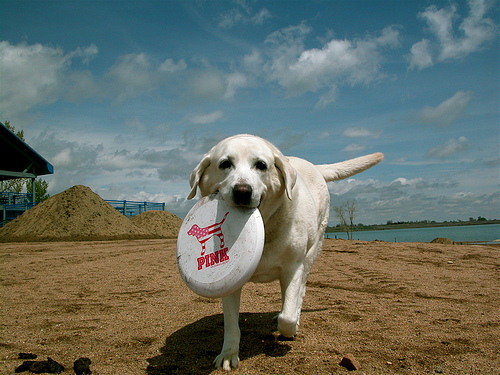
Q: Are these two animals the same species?
A: Yes, all the animals are dogs.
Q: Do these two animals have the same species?
A: Yes, all the animals are dogs.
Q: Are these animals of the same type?
A: Yes, all the animals are dogs.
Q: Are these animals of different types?
A: No, all the animals are dogs.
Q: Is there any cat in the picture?
A: No, there are no cats.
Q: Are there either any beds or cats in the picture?
A: No, there are no cats or beds.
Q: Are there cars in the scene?
A: No, there are no cars.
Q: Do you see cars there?
A: No, there are no cars.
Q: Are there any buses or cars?
A: No, there are no cars or buses.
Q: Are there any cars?
A: No, there are no cars.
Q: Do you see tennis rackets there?
A: No, there are no tennis rackets.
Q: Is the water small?
A: Yes, the water is small.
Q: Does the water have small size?
A: Yes, the water is small.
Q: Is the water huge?
A: No, the water is small.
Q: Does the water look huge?
A: No, the water is small.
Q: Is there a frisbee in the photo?
A: Yes, there is a frisbee.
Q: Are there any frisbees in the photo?
A: Yes, there is a frisbee.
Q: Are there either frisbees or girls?
A: Yes, there is a frisbee.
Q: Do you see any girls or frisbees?
A: Yes, there is a frisbee.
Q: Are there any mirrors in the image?
A: No, there are no mirrors.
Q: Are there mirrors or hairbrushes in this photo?
A: No, there are no mirrors or hairbrushes.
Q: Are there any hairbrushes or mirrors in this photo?
A: No, there are no mirrors or hairbrushes.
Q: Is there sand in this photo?
A: Yes, there is sand.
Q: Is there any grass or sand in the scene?
A: Yes, there is sand.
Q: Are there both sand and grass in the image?
A: No, there is sand but no grass.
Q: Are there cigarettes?
A: No, there are no cigarettes.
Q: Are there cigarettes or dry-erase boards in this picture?
A: No, there are no cigarettes or dry-erase boards.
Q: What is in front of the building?
A: The sand is in front of the building.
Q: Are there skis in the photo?
A: No, there are no skis.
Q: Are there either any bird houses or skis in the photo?
A: No, there are no skis or bird houses.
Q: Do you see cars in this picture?
A: No, there are no cars.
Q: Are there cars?
A: No, there are no cars.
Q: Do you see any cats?
A: No, there are no cats.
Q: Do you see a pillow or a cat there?
A: No, there are no cats or pillows.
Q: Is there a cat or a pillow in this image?
A: No, there are no cats or pillows.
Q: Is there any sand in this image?
A: Yes, there is sand.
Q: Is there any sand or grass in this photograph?
A: Yes, there is sand.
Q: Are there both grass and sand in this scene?
A: No, there is sand but no grass.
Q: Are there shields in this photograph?
A: No, there are no shields.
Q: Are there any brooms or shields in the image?
A: No, there are no shields or brooms.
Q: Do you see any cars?
A: No, there are no cars.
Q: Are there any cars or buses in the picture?
A: No, there are no cars or buses.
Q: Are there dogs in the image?
A: Yes, there is a dog.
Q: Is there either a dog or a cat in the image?
A: Yes, there is a dog.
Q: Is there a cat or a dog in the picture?
A: Yes, there is a dog.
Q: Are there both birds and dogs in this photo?
A: No, there is a dog but no birds.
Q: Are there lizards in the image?
A: No, there are no lizards.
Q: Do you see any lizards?
A: No, there are no lizards.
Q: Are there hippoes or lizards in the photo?
A: No, there are no lizards or hippoes.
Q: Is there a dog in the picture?
A: Yes, there is a dog.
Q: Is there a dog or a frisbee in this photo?
A: Yes, there is a dog.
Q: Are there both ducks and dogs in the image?
A: No, there is a dog but no ducks.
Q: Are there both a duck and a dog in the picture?
A: No, there is a dog but no ducks.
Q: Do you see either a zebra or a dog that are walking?
A: Yes, the dog is walking.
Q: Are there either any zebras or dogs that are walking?
A: Yes, the dog is walking.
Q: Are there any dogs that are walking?
A: Yes, there is a dog that is walking.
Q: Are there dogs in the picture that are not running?
A: Yes, there is a dog that is walking.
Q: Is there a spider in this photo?
A: No, there are no spiders.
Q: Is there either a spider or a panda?
A: No, there are no spiders or pandas.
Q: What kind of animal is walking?
A: The animal is a dog.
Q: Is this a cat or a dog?
A: This is a dog.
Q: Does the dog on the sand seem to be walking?
A: Yes, the dog is walking.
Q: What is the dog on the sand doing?
A: The dog is walking.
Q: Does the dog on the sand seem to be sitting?
A: No, the dog is walking.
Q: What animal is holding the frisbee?
A: The dog is holding the frisbee.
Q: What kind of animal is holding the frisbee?
A: The animal is a dog.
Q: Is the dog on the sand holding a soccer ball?
A: No, the dog is holding the frisbee.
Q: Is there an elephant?
A: No, there are no elephants.